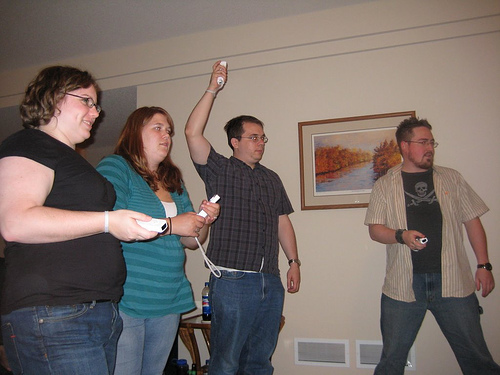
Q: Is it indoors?
A: Yes, it is indoors.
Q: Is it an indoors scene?
A: Yes, it is indoors.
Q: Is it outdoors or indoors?
A: It is indoors.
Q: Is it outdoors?
A: No, it is indoors.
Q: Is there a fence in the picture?
A: No, there are no fences.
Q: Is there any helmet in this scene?
A: No, there are no helmets.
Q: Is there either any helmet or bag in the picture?
A: No, there are no helmets or bags.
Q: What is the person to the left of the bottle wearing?
A: The person is wearing a shirt.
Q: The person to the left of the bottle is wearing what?
A: The person is wearing a shirt.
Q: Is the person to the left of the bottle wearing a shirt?
A: Yes, the person is wearing a shirt.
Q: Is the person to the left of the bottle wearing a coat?
A: No, the person is wearing a shirt.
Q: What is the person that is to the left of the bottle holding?
A: The person is holding the controller.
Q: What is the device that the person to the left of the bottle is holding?
A: The device is a controller.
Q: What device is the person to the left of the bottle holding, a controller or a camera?
A: The person is holding a controller.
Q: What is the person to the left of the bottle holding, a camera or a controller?
A: The person is holding a controller.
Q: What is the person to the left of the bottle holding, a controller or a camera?
A: The person is holding a controller.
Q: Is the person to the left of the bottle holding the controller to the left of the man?
A: Yes, the person is holding the controller.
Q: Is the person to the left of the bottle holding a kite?
A: No, the person is holding the controller.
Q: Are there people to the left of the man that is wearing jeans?
A: Yes, there is a person to the left of the man.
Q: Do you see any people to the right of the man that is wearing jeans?
A: No, the person is to the left of the man.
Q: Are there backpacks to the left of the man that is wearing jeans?
A: No, there is a person to the left of the man.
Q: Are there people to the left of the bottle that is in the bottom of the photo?
A: Yes, there is a person to the left of the bottle.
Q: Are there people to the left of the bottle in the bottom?
A: Yes, there is a person to the left of the bottle.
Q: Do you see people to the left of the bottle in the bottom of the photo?
A: Yes, there is a person to the left of the bottle.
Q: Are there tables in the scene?
A: Yes, there is a table.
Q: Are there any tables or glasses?
A: Yes, there is a table.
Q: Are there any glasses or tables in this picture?
A: Yes, there is a table.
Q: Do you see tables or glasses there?
A: Yes, there is a table.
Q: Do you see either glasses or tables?
A: Yes, there is a table.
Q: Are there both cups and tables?
A: No, there is a table but no cups.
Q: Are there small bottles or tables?
A: Yes, there is a small table.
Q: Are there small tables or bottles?
A: Yes, there is a small table.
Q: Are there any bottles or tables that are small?
A: Yes, the table is small.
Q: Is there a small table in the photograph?
A: Yes, there is a small table.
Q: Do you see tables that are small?
A: Yes, there is a table that is small.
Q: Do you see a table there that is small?
A: Yes, there is a table that is small.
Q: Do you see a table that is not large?
A: Yes, there is a small table.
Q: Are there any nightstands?
A: No, there are no nightstands.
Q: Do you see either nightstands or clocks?
A: No, there are no nightstands or clocks.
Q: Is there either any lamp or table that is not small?
A: No, there is a table but it is small.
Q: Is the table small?
A: Yes, the table is small.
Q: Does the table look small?
A: Yes, the table is small.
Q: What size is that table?
A: The table is small.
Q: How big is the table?
A: The table is small.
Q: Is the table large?
A: No, the table is small.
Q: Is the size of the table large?
A: No, the table is small.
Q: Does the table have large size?
A: No, the table is small.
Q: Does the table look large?
A: No, the table is small.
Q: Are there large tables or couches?
A: No, there is a table but it is small.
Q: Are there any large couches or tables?
A: No, there is a table but it is small.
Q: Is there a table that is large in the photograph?
A: No, there is a table but it is small.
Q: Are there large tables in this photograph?
A: No, there is a table but it is small.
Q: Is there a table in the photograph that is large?
A: No, there is a table but it is small.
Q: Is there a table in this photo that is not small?
A: No, there is a table but it is small.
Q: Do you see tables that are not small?
A: No, there is a table but it is small.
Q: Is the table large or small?
A: The table is small.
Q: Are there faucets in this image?
A: No, there are no faucets.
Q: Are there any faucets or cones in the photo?
A: No, there are no faucets or cones.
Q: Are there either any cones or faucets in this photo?
A: No, there are no faucets or cones.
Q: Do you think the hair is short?
A: Yes, the hair is short.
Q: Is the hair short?
A: Yes, the hair is short.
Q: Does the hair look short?
A: Yes, the hair is short.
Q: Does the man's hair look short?
A: Yes, the hair is short.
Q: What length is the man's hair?
A: The hair is short.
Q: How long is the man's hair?
A: The hair is short.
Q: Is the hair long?
A: No, the hair is short.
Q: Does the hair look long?
A: No, the hair is short.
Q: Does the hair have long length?
A: No, the hair is short.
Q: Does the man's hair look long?
A: No, the hair is short.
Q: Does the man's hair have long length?
A: No, the hair is short.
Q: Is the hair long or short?
A: The hair is short.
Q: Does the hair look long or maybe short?
A: The hair is short.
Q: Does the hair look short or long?
A: The hair is short.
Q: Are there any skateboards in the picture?
A: No, there are no skateboards.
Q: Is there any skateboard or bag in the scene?
A: No, there are no skateboards or bags.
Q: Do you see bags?
A: No, there are no bags.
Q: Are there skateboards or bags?
A: No, there are no bags or skateboards.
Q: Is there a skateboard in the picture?
A: No, there are no skateboards.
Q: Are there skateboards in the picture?
A: No, there are no skateboards.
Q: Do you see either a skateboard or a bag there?
A: No, there are no skateboards or bags.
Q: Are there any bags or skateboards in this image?
A: No, there are no skateboards or bags.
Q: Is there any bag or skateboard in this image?
A: No, there are no skateboards or bags.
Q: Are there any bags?
A: No, there are no bags.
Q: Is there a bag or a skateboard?
A: No, there are no bags or skateboards.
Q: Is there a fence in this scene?
A: No, there are no fences.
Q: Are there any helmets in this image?
A: No, there are no helmets.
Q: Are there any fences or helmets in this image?
A: No, there are no helmets or fences.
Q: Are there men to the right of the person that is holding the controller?
A: Yes, there is a man to the right of the person.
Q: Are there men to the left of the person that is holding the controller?
A: No, the man is to the right of the person.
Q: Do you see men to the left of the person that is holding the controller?
A: No, the man is to the right of the person.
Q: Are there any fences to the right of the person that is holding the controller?
A: No, there is a man to the right of the person.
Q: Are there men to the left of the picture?
A: Yes, there is a man to the left of the picture.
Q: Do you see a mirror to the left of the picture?
A: No, there is a man to the left of the picture.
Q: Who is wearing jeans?
A: The man is wearing jeans.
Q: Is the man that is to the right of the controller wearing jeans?
A: Yes, the man is wearing jeans.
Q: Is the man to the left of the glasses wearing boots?
A: No, the man is wearing jeans.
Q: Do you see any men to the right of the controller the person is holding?
A: Yes, there is a man to the right of the controller.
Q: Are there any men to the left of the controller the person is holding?
A: No, the man is to the right of the controller.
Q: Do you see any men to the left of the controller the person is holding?
A: No, the man is to the right of the controller.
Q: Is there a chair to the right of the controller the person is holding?
A: No, there is a man to the right of the controller.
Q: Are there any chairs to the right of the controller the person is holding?
A: No, there is a man to the right of the controller.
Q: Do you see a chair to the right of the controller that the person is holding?
A: No, there is a man to the right of the controller.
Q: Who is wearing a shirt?
A: The man is wearing a shirt.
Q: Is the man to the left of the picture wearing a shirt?
A: Yes, the man is wearing a shirt.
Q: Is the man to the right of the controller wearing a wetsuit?
A: No, the man is wearing a shirt.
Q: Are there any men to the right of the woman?
A: Yes, there is a man to the right of the woman.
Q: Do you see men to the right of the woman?
A: Yes, there is a man to the right of the woman.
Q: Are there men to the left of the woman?
A: No, the man is to the right of the woman.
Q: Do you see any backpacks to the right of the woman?
A: No, there is a man to the right of the woman.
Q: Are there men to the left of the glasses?
A: Yes, there is a man to the left of the glasses.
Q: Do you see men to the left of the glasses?
A: Yes, there is a man to the left of the glasses.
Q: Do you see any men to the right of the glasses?
A: No, the man is to the left of the glasses.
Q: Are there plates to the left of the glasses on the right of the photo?
A: No, there is a man to the left of the glasses.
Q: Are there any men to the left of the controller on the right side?
A: Yes, there is a man to the left of the controller.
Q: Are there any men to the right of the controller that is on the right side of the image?
A: No, the man is to the left of the controller.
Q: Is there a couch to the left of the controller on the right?
A: No, there is a man to the left of the controller.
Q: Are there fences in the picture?
A: No, there are no fences.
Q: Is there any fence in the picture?
A: No, there are no fences.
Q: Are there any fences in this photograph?
A: No, there are no fences.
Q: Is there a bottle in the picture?
A: Yes, there is a bottle.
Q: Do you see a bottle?
A: Yes, there is a bottle.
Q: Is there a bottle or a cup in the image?
A: Yes, there is a bottle.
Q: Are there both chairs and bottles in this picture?
A: No, there is a bottle but no chairs.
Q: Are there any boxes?
A: No, there are no boxes.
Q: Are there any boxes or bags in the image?
A: No, there are no boxes or bags.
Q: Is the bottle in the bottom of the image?
A: Yes, the bottle is in the bottom of the image.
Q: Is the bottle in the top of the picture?
A: No, the bottle is in the bottom of the image.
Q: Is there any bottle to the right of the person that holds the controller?
A: Yes, there is a bottle to the right of the person.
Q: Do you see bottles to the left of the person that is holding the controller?
A: No, the bottle is to the right of the person.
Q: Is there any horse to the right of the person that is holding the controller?
A: No, there is a bottle to the right of the person.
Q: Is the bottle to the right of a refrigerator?
A: No, the bottle is to the right of the person.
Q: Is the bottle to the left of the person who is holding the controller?
A: No, the bottle is to the right of the person.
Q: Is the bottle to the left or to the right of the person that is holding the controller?
A: The bottle is to the right of the person.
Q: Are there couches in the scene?
A: No, there are no couches.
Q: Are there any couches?
A: No, there are no couches.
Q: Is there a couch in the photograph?
A: No, there are no couches.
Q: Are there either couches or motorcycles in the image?
A: No, there are no couches or motorcycles.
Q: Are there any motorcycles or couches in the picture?
A: No, there are no couches or motorcycles.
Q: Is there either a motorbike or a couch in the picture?
A: No, there are no couches or motorcycles.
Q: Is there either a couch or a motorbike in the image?
A: No, there are no couches or motorcycles.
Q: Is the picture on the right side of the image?
A: Yes, the picture is on the right of the image.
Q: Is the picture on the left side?
A: No, the picture is on the right of the image.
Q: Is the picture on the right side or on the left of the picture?
A: The picture is on the right of the image.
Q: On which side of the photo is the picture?
A: The picture is on the right of the image.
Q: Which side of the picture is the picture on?
A: The picture is on the right of the image.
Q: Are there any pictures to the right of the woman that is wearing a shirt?
A: Yes, there is a picture to the right of the woman.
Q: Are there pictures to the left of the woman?
A: No, the picture is to the right of the woman.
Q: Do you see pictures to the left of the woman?
A: No, the picture is to the right of the woman.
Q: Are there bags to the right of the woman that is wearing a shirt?
A: No, there is a picture to the right of the woman.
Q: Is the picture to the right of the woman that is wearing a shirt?
A: Yes, the picture is to the right of the woman.